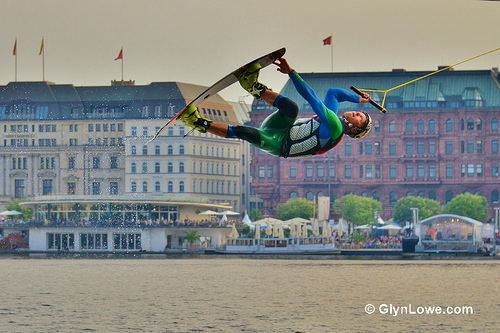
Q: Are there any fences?
A: No, there are no fences.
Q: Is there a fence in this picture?
A: No, there are no fences.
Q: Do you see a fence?
A: No, there are no fences.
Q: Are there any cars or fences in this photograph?
A: No, there are no fences or cars.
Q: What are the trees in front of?
A: The trees are in front of the building.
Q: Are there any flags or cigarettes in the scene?
A: Yes, there is a flag.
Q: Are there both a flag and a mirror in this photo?
A: No, there is a flag but no mirrors.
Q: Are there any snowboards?
A: No, there are no snowboards.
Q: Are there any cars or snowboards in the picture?
A: No, there are no snowboards or cars.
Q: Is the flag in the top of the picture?
A: Yes, the flag is in the top of the image.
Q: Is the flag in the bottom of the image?
A: No, the flag is in the top of the image.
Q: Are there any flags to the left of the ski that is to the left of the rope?
A: Yes, there is a flag to the left of the ski.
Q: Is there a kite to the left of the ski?
A: No, there is a flag to the left of the ski.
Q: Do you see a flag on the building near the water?
A: Yes, there is a flag on the building.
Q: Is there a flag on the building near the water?
A: Yes, there is a flag on the building.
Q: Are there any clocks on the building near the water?
A: No, there is a flag on the building.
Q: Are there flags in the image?
A: Yes, there is a flag.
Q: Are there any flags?
A: Yes, there is a flag.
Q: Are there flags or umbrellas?
A: Yes, there is a flag.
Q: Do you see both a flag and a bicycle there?
A: No, there is a flag but no bicycles.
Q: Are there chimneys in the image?
A: No, there are no chimneys.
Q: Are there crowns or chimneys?
A: No, there are no chimneys or crowns.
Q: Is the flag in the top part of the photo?
A: Yes, the flag is in the top of the image.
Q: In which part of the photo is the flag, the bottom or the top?
A: The flag is in the top of the image.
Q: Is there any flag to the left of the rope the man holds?
A: Yes, there is a flag to the left of the rope.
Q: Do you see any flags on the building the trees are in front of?
A: Yes, there is a flag on the building.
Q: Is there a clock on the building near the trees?
A: No, there is a flag on the building.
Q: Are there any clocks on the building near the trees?
A: No, there is a flag on the building.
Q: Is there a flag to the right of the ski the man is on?
A: Yes, there is a flag to the right of the ski.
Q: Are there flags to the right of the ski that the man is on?
A: Yes, there is a flag to the right of the ski.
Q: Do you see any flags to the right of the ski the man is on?
A: Yes, there is a flag to the right of the ski.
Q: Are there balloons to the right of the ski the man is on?
A: No, there is a flag to the right of the ski.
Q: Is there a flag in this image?
A: Yes, there is a flag.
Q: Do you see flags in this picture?
A: Yes, there is a flag.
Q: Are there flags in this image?
A: Yes, there is a flag.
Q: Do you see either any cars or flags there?
A: Yes, there is a flag.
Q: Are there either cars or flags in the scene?
A: Yes, there is a flag.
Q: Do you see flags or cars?
A: Yes, there is a flag.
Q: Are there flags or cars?
A: Yes, there is a flag.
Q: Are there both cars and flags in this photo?
A: No, there is a flag but no cars.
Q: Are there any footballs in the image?
A: No, there are no footballs.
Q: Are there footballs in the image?
A: No, there are no footballs.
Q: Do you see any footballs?
A: No, there are no footballs.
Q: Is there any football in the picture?
A: No, there are no footballs.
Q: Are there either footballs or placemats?
A: No, there are no footballs or placemats.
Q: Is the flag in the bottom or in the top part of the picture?
A: The flag is in the top of the image.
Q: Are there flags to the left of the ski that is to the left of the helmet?
A: Yes, there is a flag to the left of the ski.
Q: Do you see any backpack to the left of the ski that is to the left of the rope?
A: No, there is a flag to the left of the ski.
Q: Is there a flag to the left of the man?
A: Yes, there is a flag to the left of the man.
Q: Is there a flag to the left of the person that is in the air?
A: Yes, there is a flag to the left of the man.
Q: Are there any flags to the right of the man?
A: No, the flag is to the left of the man.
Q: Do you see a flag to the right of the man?
A: No, the flag is to the left of the man.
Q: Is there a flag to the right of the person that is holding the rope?
A: No, the flag is to the left of the man.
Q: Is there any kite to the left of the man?
A: No, there is a flag to the left of the man.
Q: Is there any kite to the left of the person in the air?
A: No, there is a flag to the left of the man.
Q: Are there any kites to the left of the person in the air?
A: No, there is a flag to the left of the man.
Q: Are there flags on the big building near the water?
A: Yes, there is a flag on the building.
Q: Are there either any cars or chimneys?
A: No, there are no cars or chimneys.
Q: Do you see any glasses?
A: No, there are no glasses.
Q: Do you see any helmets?
A: Yes, there is a helmet.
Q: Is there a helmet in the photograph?
A: Yes, there is a helmet.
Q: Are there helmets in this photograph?
A: Yes, there is a helmet.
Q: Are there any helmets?
A: Yes, there is a helmet.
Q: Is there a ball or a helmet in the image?
A: Yes, there is a helmet.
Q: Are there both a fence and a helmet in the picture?
A: No, there is a helmet but no fences.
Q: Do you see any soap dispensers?
A: No, there are no soap dispensers.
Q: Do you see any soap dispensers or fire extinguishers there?
A: No, there are no soap dispensers or fire extinguishers.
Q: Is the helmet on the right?
A: Yes, the helmet is on the right of the image.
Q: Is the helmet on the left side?
A: No, the helmet is on the right of the image.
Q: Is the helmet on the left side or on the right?
A: The helmet is on the right of the image.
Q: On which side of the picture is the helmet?
A: The helmet is on the right of the image.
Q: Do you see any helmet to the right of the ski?
A: Yes, there is a helmet to the right of the ski.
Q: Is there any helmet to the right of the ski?
A: Yes, there is a helmet to the right of the ski.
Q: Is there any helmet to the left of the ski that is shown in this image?
A: No, the helmet is to the right of the ski.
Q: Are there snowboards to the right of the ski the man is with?
A: No, there is a helmet to the right of the ski.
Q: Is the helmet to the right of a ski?
A: Yes, the helmet is to the right of a ski.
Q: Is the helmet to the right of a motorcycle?
A: No, the helmet is to the right of a ski.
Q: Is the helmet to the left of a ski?
A: No, the helmet is to the right of a ski.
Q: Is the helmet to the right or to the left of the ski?
A: The helmet is to the right of the ski.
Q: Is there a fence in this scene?
A: No, there are no fences.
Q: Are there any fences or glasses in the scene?
A: No, there are no fences or glasses.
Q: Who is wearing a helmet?
A: The man is wearing a helmet.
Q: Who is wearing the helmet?
A: The man is wearing a helmet.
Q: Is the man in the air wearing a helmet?
A: Yes, the man is wearing a helmet.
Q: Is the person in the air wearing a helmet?
A: Yes, the man is wearing a helmet.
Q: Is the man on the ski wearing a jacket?
A: No, the man is wearing a helmet.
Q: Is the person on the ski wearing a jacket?
A: No, the man is wearing a helmet.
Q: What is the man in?
A: The man is in the air.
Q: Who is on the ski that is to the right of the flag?
A: The man is on the ski.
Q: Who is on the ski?
A: The man is on the ski.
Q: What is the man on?
A: The man is on the ski.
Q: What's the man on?
A: The man is on the ski.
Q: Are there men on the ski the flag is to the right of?
A: Yes, there is a man on the ski.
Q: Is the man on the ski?
A: Yes, the man is on the ski.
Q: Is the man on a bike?
A: No, the man is on the ski.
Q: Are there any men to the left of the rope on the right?
A: Yes, there is a man to the left of the rope.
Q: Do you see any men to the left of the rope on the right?
A: Yes, there is a man to the left of the rope.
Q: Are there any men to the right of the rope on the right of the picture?
A: No, the man is to the left of the rope.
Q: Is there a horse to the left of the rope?
A: No, there is a man to the left of the rope.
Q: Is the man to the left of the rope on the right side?
A: Yes, the man is to the left of the rope.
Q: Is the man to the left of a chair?
A: No, the man is to the left of the rope.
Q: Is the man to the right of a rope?
A: No, the man is to the left of a rope.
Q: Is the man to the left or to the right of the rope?
A: The man is to the left of the rope.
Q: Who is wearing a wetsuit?
A: The man is wearing a wetsuit.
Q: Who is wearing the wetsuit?
A: The man is wearing a wetsuit.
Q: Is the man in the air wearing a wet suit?
A: Yes, the man is wearing a wet suit.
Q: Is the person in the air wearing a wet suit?
A: Yes, the man is wearing a wet suit.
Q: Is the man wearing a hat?
A: No, the man is wearing a wet suit.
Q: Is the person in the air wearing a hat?
A: No, the man is wearing a wet suit.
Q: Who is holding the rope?
A: The man is holding the rope.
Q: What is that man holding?
A: The man is holding the rope.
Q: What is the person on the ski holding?
A: The man is holding the rope.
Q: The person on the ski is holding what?
A: The man is holding the rope.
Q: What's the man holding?
A: The man is holding the rope.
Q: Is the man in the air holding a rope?
A: Yes, the man is holding a rope.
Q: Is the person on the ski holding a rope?
A: Yes, the man is holding a rope.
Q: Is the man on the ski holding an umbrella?
A: No, the man is holding a rope.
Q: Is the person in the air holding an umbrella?
A: No, the man is holding a rope.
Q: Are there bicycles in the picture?
A: No, there are no bicycles.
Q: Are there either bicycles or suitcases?
A: No, there are no bicycles or suitcases.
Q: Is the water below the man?
A: Yes, the water is below the man.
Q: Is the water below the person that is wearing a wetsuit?
A: Yes, the water is below the man.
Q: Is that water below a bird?
A: No, the water is below the man.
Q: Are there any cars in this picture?
A: No, there are no cars.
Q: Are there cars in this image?
A: No, there are no cars.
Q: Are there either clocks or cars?
A: No, there are no cars or clocks.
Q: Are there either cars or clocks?
A: No, there are no cars or clocks.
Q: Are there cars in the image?
A: No, there are no cars.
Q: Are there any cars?
A: No, there are no cars.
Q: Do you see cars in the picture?
A: No, there are no cars.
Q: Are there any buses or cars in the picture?
A: No, there are no cars or buses.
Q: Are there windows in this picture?
A: Yes, there is a window.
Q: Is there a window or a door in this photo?
A: Yes, there is a window.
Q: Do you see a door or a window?
A: Yes, there is a window.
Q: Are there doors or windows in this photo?
A: Yes, there is a window.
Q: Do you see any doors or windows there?
A: Yes, there is a window.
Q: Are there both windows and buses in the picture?
A: No, there is a window but no buses.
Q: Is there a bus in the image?
A: No, there are no buses.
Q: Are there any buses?
A: No, there are no buses.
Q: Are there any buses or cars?
A: No, there are no buses or cars.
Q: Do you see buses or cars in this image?
A: No, there are no buses or cars.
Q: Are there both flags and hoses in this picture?
A: No, there is a flag but no hoses.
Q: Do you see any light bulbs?
A: No, there are no light bulbs.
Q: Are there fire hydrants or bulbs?
A: No, there are no bulbs or fire hydrants.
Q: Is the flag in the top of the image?
A: Yes, the flag is in the top of the image.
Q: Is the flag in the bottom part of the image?
A: No, the flag is in the top of the image.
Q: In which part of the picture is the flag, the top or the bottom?
A: The flag is in the top of the image.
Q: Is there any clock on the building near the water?
A: No, there is a flag on the building.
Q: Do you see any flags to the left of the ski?
A: Yes, there is a flag to the left of the ski.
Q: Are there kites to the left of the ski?
A: No, there is a flag to the left of the ski.